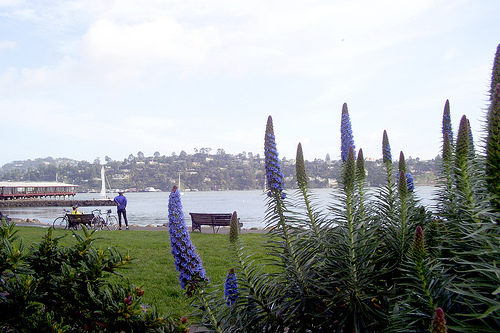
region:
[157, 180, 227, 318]
cone shaped flower on the plant.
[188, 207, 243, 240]
Bench by the water.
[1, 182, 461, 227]
Water in the background.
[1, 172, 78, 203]
covered pier in the background.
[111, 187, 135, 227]
Man standing by the water.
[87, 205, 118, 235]
bicycle by the man.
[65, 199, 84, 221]
Person sitting on the bench.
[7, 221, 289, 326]
Green grass covering the ground.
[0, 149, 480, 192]
Mountains in the background.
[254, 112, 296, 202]
Purple blue coloring on the flowers.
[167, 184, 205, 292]
the bright purple flowering flower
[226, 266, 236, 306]
the bright purple flowering flower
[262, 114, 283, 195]
the bright purple flowering flower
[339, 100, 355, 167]
the bright purple flowering flower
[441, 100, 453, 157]
the bright purple flowering flower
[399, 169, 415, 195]
the bright purple flowering flower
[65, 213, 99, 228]
the brown and black wooden bench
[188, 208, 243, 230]
the brown and black wooden bench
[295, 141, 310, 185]
the green almost flowering flower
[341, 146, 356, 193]
the green almost flowering flower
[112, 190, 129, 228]
a person standing by the water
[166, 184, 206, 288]
a cone of flowers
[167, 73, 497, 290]
the flowers are in bloom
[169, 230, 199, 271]
purple flowers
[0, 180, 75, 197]
building by the water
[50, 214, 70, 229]
a bicycle wheel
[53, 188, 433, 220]
large body of water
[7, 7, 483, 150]
the sky is cloudy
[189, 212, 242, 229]
a bench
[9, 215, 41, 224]
rocks by the water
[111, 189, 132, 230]
person looking at the water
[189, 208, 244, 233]
empty wooden bench near water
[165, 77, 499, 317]
plants with purple flowers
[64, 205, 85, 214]
person sitting on bench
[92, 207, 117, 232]
bicycle next to bench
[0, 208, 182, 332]
green and yellow shrub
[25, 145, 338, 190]
hillside with houses near water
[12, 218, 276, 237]
walk way along water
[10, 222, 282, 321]
grassy area near water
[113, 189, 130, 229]
person with their hands behind their back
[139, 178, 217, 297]
the flowers are purple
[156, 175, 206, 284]
the flowers are purple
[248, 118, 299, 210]
the flowers are purple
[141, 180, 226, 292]
the flowers are purple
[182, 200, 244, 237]
bench facing the water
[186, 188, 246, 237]
bench facing the water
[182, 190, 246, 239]
bench facing the water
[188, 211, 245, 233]
A bench.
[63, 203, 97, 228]
A person sitting on a bench.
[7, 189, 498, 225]
A body of water.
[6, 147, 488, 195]
A hillside.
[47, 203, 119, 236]
Bicycles.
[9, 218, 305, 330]
A patch of grass.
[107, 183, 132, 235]
A person standing by a bicycle.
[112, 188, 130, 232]
A person wearing a long sleeved purple shirt.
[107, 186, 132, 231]
man wearing all purple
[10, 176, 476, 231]
body of water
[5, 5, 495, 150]
sky with white clouds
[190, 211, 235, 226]
wooden bench near water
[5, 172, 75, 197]
building in water